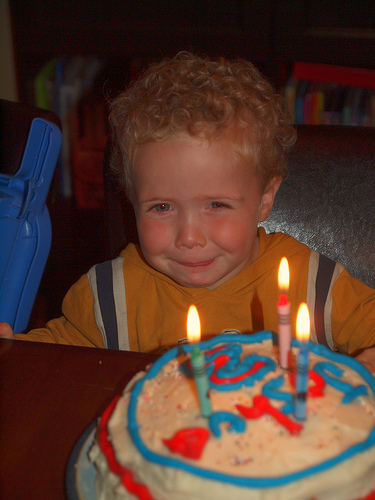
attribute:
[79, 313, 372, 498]
cake — small, birthday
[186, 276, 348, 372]
candles — three, lit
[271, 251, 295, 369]
candle — birthday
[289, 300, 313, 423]
candle — birthday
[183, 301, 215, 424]
candle — birthday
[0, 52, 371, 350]
boy — smiling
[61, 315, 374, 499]
birthday cake — small, round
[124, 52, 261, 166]
hair — curly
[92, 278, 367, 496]
cake — small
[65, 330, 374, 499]
cake — birthday, red, white, and blue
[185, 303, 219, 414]
candles — three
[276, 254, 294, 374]
candles — three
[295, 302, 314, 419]
candles — three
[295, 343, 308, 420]
candles — crayon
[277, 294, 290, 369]
candles — crayon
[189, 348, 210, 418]
candles — crayon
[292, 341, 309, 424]
candle — birthday, blue crayon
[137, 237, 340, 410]
candles — lit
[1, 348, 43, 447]
table — wood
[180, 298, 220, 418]
candle — green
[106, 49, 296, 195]
hair — blonde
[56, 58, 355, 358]
boy — little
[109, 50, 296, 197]
curly hair — blonde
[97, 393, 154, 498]
icing — red